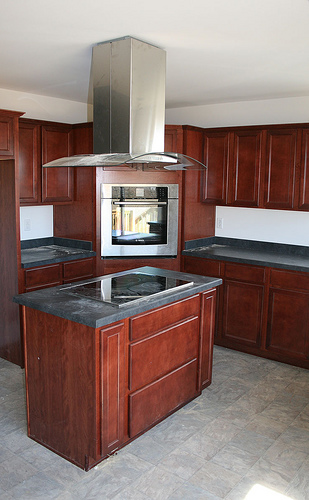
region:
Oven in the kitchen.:
[97, 183, 178, 261]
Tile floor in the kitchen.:
[4, 346, 307, 498]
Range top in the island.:
[57, 267, 200, 302]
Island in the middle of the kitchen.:
[11, 261, 234, 469]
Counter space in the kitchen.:
[183, 233, 307, 273]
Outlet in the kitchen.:
[217, 217, 223, 231]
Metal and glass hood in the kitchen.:
[41, 36, 206, 172]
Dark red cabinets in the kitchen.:
[0, 108, 303, 472]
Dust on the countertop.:
[21, 244, 124, 315]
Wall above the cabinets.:
[0, 88, 308, 124]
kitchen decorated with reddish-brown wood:
[10, 18, 292, 463]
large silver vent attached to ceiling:
[34, 27, 204, 195]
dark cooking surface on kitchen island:
[52, 257, 190, 319]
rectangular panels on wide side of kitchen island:
[79, 278, 242, 447]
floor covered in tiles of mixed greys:
[202, 401, 290, 472]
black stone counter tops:
[180, 230, 300, 263]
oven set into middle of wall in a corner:
[82, 167, 190, 263]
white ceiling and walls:
[11, 11, 287, 235]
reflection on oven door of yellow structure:
[101, 193, 173, 248]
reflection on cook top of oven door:
[57, 258, 195, 306]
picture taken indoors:
[20, 12, 307, 453]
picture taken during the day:
[29, 66, 283, 288]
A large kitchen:
[9, 92, 308, 379]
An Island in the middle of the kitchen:
[4, 224, 229, 449]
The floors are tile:
[89, 476, 216, 494]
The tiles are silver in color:
[133, 476, 237, 491]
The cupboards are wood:
[213, 133, 284, 194]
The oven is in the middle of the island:
[18, 350, 250, 485]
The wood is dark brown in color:
[62, 352, 128, 417]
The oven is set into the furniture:
[92, 175, 203, 269]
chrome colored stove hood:
[42, 35, 209, 165]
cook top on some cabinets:
[11, 266, 220, 470]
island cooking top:
[13, 266, 223, 470]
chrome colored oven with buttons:
[98, 183, 178, 254]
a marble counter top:
[186, 235, 307, 271]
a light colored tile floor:
[0, 345, 306, 498]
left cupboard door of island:
[100, 331, 124, 448]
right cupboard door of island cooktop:
[199, 286, 214, 391]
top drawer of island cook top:
[128, 295, 198, 342]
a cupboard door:
[232, 131, 262, 207]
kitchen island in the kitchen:
[24, 252, 254, 481]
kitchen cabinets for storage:
[190, 127, 307, 222]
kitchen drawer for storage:
[226, 258, 305, 291]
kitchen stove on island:
[75, 260, 207, 310]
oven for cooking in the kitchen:
[101, 183, 183, 259]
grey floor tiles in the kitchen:
[231, 364, 305, 491]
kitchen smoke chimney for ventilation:
[60, 31, 200, 188]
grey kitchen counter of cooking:
[200, 231, 308, 273]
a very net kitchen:
[3, 20, 268, 473]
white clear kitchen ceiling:
[12, 10, 279, 126]